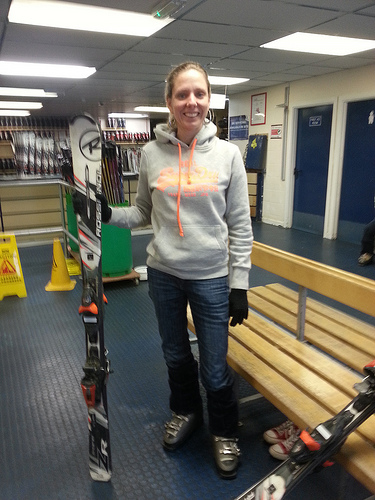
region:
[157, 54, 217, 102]
Woman has light hair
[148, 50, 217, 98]
Woman's hair is straight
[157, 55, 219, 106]
Woman's hair is short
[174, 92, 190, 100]
Woman has dark eye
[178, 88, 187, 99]
Woman's eye is open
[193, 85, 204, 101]
Woman has dark eye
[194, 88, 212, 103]
Woman's eye is open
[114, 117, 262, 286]
Woman wearing white hoodie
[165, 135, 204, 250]
White hoodie has orange tie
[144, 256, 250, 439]
Woman wearing denim pants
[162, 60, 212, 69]
Woman has blonde hair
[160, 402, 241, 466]
Woman is wearing grey sneakers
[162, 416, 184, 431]
Sneakers has white strings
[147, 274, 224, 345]
Woman wearing blue jeans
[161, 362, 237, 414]
Woman wearing black leg warmers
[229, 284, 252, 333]
Woman wearing black gloves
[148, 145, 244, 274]
Woman wearing grey sweater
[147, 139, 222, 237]
Orange print on shirt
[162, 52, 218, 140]
Smile on woman's face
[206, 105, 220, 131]
Woman wearing silver earrings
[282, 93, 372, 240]
two blue and white doors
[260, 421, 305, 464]
pair red and white sneakers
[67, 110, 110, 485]
black white and orange ski in the woman's hand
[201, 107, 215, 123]
large silver hoop earring hanging from woman's ear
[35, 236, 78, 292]
yellow cone on the floor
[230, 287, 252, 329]
black glove on the woman's hand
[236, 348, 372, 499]
ski on the wooden bench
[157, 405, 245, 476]
silver footwear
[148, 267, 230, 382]
blue jeans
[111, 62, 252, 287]
woman wearing a gray hoodie with a neon orange graphic on it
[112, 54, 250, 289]
woman wearing a grey pullover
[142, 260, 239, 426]
woman wearing blue jeans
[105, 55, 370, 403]
woman standing beside bench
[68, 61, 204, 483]
ski being held by woman's right hand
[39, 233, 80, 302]
a yellow cone on the ground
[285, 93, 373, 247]
large blue doors in wall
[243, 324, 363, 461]
red and white shoes beneath bench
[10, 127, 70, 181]
skis lined up against the wall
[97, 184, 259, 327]
woman wearing black gloves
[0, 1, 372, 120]
florescent lights in the ceiling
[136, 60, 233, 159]
The woman is smiling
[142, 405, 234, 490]
The woman has ski boots on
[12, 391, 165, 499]
The floor is blue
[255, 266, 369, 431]
The bench is wooden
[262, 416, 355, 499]
The sneakers are under the bench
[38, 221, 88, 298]
The cones are yellow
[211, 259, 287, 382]
The woman has gloves on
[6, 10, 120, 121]
The lights are on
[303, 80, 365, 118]
The walls are off white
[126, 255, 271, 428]
The woman has jeans on